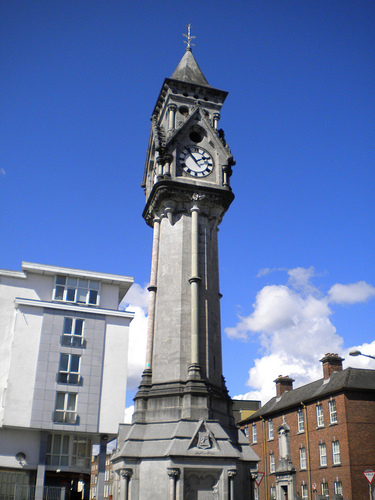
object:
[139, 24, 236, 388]
clock tower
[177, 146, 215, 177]
clock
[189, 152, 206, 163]
1:54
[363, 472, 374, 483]
sign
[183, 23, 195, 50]
weather vane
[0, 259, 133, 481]
building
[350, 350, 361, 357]
street light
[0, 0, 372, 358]
sky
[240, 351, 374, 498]
building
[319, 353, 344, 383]
chimney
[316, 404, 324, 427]
windows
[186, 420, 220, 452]
triangle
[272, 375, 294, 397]
chimney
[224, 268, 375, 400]
clouds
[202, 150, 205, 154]
numbers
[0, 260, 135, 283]
top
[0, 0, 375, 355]
background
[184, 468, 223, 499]
door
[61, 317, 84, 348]
window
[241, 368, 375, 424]
roof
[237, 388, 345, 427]
gutter